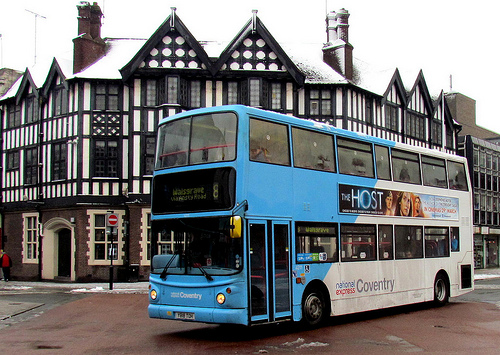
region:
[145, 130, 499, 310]
blue and white double decker bus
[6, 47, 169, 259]
brown and white two story house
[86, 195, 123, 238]
red and white sign on pole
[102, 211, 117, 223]
white dash is on red sign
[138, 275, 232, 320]
white headlights on front of blue bus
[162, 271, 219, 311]
white company name on front of bus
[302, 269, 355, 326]
black tires on bus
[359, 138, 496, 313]
back half of bus is white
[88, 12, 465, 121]
black and white gables on roof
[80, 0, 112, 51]
red brick chimney on roof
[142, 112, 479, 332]
a blue and white bus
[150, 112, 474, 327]
a double decker public service bus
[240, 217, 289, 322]
a bus entry exit door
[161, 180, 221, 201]
a bus electric destination sign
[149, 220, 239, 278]
a bus windshield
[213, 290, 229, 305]
a bus left headlight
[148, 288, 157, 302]
a bus right headlight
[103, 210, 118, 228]
a do not enter traffic sign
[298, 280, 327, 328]
a bus front left tire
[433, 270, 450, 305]
a bus rear right tire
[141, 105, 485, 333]
A double decker bus moving forward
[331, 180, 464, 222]
An advertisement on the side of the bus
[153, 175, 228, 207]
The destination of where the bus is going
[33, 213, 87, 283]
An archway to the building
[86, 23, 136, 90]
Snow on top the building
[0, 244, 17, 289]
A person standing by the building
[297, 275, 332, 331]
The tire of the bus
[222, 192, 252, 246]
The rear view mirror of the bus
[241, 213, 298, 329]
The front door of the bus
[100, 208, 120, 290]
The red and white stop sign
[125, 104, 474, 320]
a double decker bus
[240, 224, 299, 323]
a double door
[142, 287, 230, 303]
front head lights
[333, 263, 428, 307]
writing on the side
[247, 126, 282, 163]
people in window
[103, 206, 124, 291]
a sign on a pole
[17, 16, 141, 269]
a build along the street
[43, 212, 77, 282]
a door on the building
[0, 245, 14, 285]
a person standing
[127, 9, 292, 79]
a trinagle roof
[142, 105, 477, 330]
Blue double decker bus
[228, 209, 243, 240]
Yellow side mirror on blue bus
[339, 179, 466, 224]
TV show banner on bus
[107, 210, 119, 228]
Circular red and white traffic sign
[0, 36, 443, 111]
Roofer covered in snow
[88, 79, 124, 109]
Window on black and white building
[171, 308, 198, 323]
White license plate on bus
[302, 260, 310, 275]
Handicap sticker on bus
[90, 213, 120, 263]
Window behind traffic sign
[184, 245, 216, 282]
Black windshield on window of bus